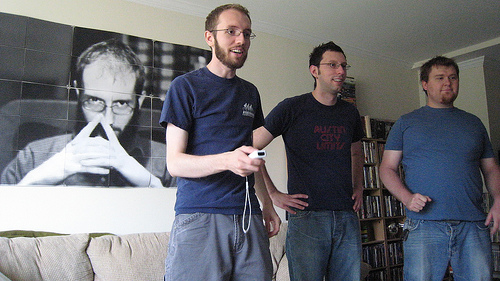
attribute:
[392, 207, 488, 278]
jeans — blue 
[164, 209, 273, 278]
pants — gray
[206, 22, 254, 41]
glasses — clear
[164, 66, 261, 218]
t-shirt — blue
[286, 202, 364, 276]
jeans — blue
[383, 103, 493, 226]
shirt — blue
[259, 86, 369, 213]
shirt — dark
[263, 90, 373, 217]
tee shirt — blue 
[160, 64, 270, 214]
tee shirt — blue 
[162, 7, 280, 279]
man — fat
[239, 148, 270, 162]
controller — game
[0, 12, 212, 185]
photograph — large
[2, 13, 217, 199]
photo — large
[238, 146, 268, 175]
control — white, game controller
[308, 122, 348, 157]
red words — red 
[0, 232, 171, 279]
two pillows — White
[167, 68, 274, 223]
shirt — blue 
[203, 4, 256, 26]
hair — brown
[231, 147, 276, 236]
controller — white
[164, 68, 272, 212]
shirt — blue